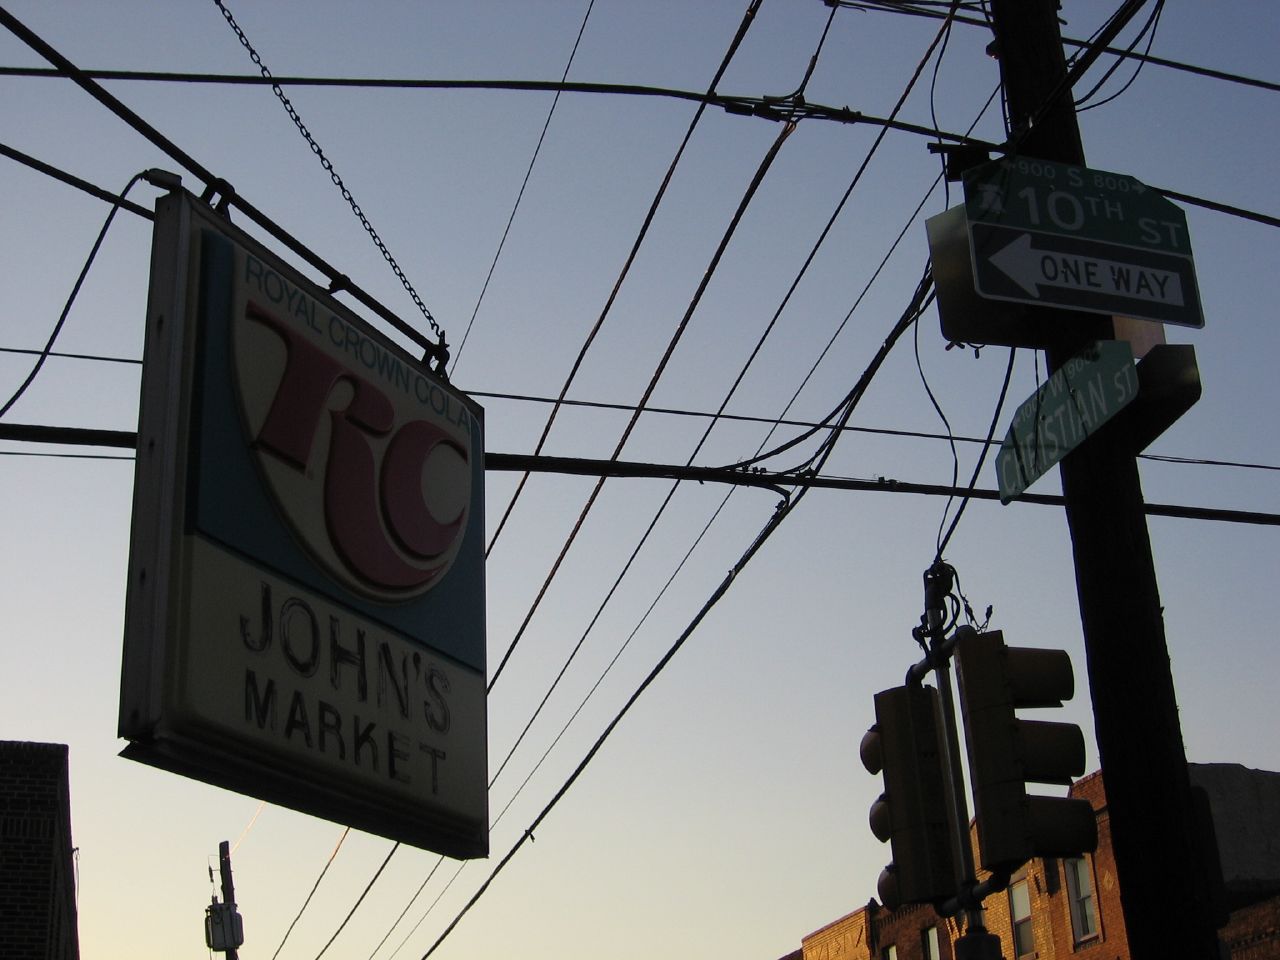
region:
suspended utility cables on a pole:
[12, 4, 1277, 653]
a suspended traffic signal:
[839, 510, 1102, 915]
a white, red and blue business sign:
[82, 132, 524, 865]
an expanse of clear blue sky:
[0, 10, 1270, 759]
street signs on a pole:
[890, 120, 1210, 483]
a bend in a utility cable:
[698, 369, 882, 513]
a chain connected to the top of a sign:
[199, 0, 489, 387]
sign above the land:
[19, 203, 622, 883]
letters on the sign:
[213, 316, 523, 612]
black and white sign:
[933, 194, 1225, 378]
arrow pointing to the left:
[876, 210, 1216, 416]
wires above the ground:
[428, 165, 908, 629]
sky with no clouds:
[668, 549, 872, 843]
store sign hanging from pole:
[82, 187, 517, 870]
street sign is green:
[949, 140, 1195, 268]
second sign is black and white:
[960, 209, 1212, 342]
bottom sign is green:
[974, 334, 1144, 509]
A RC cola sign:
[101, 185, 492, 876]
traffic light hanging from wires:
[860, 280, 1103, 916]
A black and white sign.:
[957, 221, 1211, 363]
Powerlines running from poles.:
[3, 3, 1277, 946]